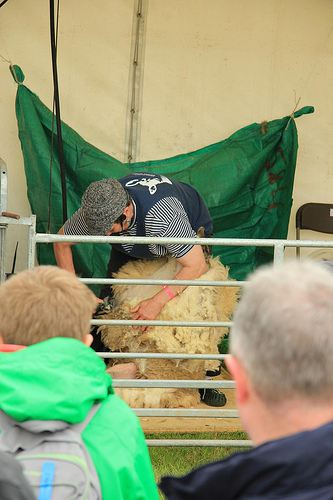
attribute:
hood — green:
[0, 335, 111, 423]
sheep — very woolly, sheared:
[71, 250, 255, 410]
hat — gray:
[80, 177, 127, 234]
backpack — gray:
[0, 419, 100, 498]